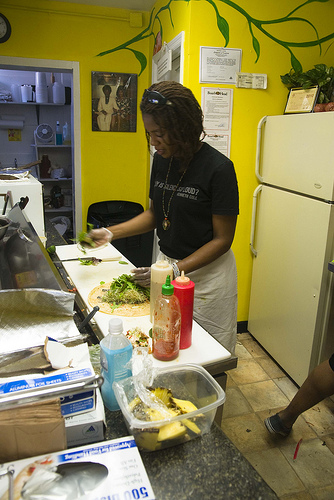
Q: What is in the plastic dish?
A: Pineapple.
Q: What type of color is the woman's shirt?
A: Black.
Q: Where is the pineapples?
A: In a plastic container.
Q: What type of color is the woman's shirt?
A: Black.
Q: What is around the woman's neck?
A: Necklace.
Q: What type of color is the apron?
A: Beige.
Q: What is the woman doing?
A: Preparing food.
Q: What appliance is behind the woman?
A: Refrigerator.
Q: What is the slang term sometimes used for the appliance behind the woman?
A: Fridge.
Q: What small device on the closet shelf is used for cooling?
A: Fan.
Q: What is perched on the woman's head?
A: Sunglasses.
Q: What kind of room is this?
A: Kitchen.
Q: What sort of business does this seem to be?
A: Restaurant.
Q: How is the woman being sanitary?
A: Wearing gloves.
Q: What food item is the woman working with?
A: Lettuce.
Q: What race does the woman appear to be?
A: Black.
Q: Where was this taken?
A: A kitchen.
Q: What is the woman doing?
A: Preparing food.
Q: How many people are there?
A: One.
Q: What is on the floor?
A: Tile.